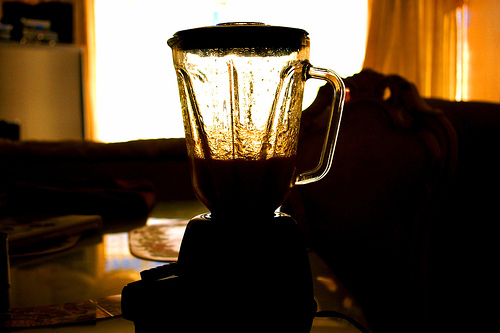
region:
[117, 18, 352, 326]
blender silhouetted against lit window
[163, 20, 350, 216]
glass pitcher on black stand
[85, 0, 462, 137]
window lit from outside with open curtains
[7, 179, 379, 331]
shiny white counter top with kitchen appliances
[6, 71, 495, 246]
large sofa in background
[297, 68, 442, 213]
man sitting on couch with hands to head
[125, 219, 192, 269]
white plastic placemat with green edges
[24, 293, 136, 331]
paperwork sitting on white counter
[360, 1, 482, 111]
white curtains open over sunny window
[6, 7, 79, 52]
wooden shelf with books hanging on wall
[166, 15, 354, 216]
clear part of a blender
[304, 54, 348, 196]
glass handle on a blender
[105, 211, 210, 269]
placemat on a table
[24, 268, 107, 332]
napkins on a table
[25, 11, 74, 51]
things on a shelf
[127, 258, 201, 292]
buttons on a blender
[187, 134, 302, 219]
liquid in a blender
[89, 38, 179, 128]
sunlight through the window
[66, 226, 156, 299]
reflection from a window on the table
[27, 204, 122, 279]
stacks of stuff on a table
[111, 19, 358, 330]
silhouette of blender with glass pitcher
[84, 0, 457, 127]
window in distance letting in golden light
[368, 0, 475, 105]
open off white curtains covering window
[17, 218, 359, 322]
glossy counter top in kitchen near living room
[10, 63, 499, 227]
outline of sofa in background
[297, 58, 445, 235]
man sitting on sofa holding hands to head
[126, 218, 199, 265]
placemat decorated with green vines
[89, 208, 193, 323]
golden sunlight reflected off of counter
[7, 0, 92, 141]
white walls with white shelf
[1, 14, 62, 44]
stacks of books and cds on white wall shelf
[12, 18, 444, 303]
this photo is dimly lit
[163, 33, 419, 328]
this is a blender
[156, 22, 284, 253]
this is an appliance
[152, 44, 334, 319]
the appliance is silhouetted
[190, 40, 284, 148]
this is made of glass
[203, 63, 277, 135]
the glass is transparent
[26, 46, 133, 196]
the background is blurry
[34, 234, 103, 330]
the table is glass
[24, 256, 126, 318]
the table is reflective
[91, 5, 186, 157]
the window is very bright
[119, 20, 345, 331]
A blender on a table.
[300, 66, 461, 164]
A person in the dark.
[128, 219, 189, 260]
Part of a place mat.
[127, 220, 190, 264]
A place mat on a table.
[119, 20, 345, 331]
A blender in the dark.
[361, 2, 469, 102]
A curtain on a window.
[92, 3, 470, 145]
A blurry glass window.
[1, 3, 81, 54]
Books on a shelf.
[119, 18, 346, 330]
Liquid in a blender.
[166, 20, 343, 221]
The pitcher of a blender.